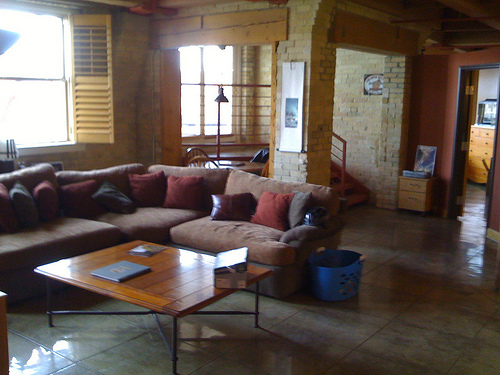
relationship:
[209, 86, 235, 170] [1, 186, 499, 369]
lamp on floor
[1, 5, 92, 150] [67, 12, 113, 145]
window has shudder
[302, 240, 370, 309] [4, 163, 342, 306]
pail next to couch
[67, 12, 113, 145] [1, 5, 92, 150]
shudder inside window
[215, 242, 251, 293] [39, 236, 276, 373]
box on table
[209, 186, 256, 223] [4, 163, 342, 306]
pillow on top of couch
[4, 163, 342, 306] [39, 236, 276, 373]
couch next to table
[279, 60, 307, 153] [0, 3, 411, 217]
calender on wall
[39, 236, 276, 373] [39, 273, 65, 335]
table has leg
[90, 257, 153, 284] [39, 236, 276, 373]
book on top of table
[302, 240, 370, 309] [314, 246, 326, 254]
pail has handle